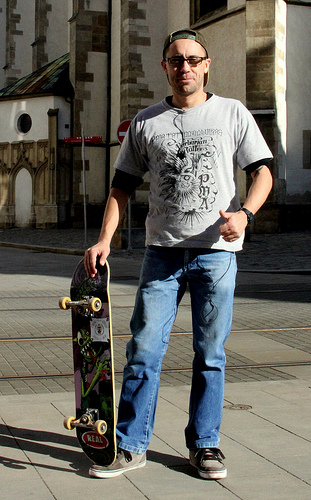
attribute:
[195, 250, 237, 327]
cord — black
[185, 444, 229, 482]
shoe — laced, gray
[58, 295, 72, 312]
wheel — yellow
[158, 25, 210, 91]
cap — green, backwards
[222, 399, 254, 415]
grate — small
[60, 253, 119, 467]
skateboard — colorful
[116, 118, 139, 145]
sign — red, white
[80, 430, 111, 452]
sticker — red, white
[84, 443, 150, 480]
sneaker — laced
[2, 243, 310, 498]
street — bricked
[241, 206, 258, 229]
watch — black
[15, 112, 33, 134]
window — round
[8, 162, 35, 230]
door — sealed, arched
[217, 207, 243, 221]
thumb — pointed upwards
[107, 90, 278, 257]
shirt — gray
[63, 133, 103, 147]
sign — red, white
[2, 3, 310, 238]
building — bricked